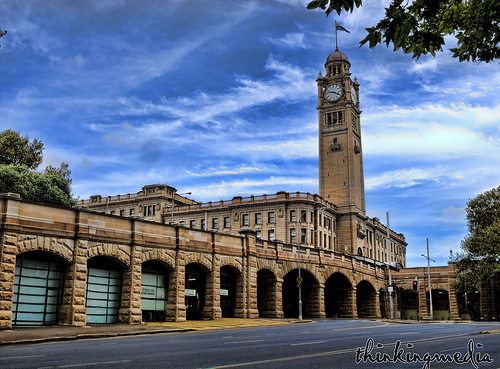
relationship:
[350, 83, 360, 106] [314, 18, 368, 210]
clock on clock tower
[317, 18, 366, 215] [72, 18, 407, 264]
clock tower on building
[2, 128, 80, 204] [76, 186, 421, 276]
tree behind building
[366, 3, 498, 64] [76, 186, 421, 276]
tree behind building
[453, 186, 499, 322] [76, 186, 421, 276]
tree behind building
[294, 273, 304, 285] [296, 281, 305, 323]
sign on pole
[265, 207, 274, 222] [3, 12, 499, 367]
window on building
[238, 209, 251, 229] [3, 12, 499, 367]
window on building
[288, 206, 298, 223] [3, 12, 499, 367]
window on building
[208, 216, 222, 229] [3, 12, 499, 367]
window on building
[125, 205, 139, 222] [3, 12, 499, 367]
window on building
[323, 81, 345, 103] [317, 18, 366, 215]
clock on clock tower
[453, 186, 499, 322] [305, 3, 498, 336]
tree covering tree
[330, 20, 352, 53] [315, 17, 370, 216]
flag on tower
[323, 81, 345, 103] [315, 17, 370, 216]
clock on tower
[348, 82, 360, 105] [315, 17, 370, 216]
clock on tower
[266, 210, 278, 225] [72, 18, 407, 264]
window on building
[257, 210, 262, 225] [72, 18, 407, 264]
window on building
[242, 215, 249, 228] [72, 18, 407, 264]
window on building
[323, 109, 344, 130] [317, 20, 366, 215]
windows on clock tower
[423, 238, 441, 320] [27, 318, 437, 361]
pole beside road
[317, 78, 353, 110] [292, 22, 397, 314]
clock on building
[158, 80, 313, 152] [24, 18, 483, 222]
cloud in sky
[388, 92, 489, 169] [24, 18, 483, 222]
cloud in sky